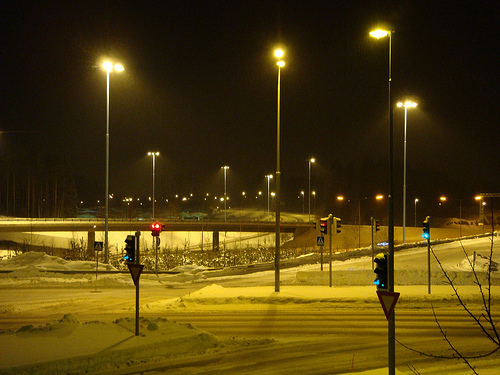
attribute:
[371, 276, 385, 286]
light — green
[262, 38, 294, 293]
streetlight — tall, thin, illuminated 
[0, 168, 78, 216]
tree trunks — tall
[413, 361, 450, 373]
signal — green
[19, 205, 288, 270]
overpass — elevated 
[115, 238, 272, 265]
plants — dry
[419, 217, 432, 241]
greenlight signal — green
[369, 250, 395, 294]
greenlight signal — green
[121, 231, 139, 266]
greenlight signal — green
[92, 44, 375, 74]
lamp — Tall 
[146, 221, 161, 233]
lights — red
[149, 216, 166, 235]
lights — red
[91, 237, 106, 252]
sign — small , black , white 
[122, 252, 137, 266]
light — green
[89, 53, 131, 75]
lights — brightly lit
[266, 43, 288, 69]
lights — brightly lit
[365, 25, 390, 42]
lights — brightly lit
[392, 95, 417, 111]
lights — brightly lit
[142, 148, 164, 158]
lights — brightly lit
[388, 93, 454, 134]
signal — green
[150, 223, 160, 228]
lights — red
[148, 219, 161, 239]
light — red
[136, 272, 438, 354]
road — snowplowed 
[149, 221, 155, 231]
light — red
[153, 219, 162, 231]
light — red